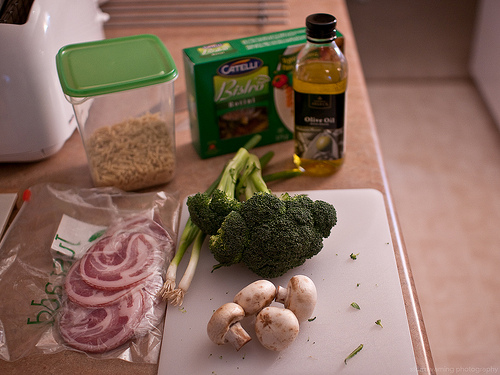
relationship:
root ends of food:
[160, 256, 196, 306] [186, 147, 338, 279]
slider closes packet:
[20, 186, 33, 201] [5, 176, 179, 367]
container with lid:
[55, 34, 180, 192] [53, 31, 176, 95]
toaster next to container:
[4, 2, 108, 164] [55, 34, 180, 192]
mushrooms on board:
[191, 274, 323, 372] [156, 188, 419, 375]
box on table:
[184, 28, 348, 145] [111, 6, 434, 371]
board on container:
[184, 189, 445, 356] [55, 34, 180, 192]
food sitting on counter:
[11, 9, 351, 351] [0, 0, 436, 375]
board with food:
[156, 188, 419, 375] [186, 147, 338, 279]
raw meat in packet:
[52, 212, 175, 354] [5, 176, 179, 367]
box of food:
[181, 27, 344, 160] [185, 144, 356, 276]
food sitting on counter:
[202, 146, 299, 261] [6, 9, 439, 372]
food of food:
[186, 147, 338, 279] [186, 147, 338, 279]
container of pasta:
[50, 28, 183, 192] [81, 110, 177, 191]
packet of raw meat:
[5, 176, 179, 367] [59, 215, 175, 353]